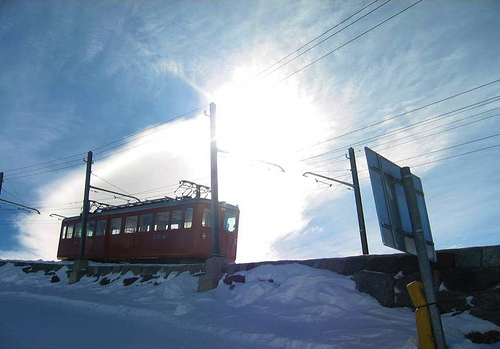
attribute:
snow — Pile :
[176, 284, 383, 344]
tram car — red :
[56, 196, 243, 271]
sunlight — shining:
[213, 70, 371, 172]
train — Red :
[48, 183, 240, 280]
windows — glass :
[59, 202, 238, 240]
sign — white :
[365, 145, 447, 347]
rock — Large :
[352, 269, 394, 307]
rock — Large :
[225, 275, 245, 287]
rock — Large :
[121, 276, 137, 284]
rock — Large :
[50, 274, 59, 281]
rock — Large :
[97, 277, 111, 285]